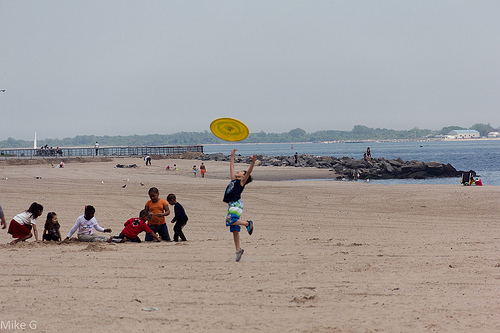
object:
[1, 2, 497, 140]
sky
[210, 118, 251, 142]
frisbee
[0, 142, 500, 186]
water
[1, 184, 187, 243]
people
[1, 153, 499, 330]
sand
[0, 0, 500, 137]
air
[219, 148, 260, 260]
person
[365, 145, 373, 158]
person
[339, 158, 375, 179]
rocks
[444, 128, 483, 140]
building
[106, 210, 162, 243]
boy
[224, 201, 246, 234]
shorts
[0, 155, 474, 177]
expanse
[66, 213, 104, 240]
outfit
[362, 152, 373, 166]
girl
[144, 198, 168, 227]
t-shirt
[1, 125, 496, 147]
tree line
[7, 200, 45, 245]
person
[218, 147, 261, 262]
boy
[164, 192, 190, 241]
over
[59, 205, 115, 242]
child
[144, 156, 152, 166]
adult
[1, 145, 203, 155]
pier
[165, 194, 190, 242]
person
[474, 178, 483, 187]
cooler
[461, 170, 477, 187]
person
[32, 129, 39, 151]
boat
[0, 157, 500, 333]
beach